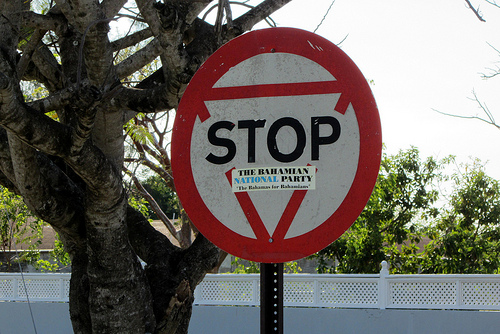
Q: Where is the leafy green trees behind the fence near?
A: A stop sign.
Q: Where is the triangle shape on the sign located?
A: Bottom of sign.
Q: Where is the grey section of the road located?
A: Near stop sign.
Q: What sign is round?
A: Stop sign.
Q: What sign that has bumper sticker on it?
A: The stop sign.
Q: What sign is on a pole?
A: Stop sign.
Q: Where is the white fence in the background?
A: Behind the trees.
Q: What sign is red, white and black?
A: Stop sign.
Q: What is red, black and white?
A: A stop sign.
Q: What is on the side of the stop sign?
A: A large tree.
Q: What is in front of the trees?
A: A white fence.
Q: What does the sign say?
A: STOP.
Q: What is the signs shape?
A: Circle.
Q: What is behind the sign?
A: A tree.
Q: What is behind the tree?
A: A white fence.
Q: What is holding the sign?
A: A metal pole.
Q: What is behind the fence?
A: Green trees.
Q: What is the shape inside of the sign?
A: A triangle.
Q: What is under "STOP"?
A: The Bahamian national party sign.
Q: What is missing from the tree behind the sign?
A: Leaves.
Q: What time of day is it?
A: Mid-afternoon.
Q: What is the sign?
A: A stop sign.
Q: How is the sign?
A: With big black lettering.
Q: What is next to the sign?
A: A big tree.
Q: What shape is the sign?
A: Circular.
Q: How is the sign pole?
A: Metal.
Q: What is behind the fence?
A: Green trees.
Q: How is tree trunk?
A: A brown.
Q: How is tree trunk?
A: Twisted.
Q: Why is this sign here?
A: To tell drivers to stop.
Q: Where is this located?
A: On a street.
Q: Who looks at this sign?
A: Drivers.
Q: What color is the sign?
A: Red and white.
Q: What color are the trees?
A: Green.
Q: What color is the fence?
A: White.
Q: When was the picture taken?
A: Daylight hours.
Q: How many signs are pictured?
A: One.